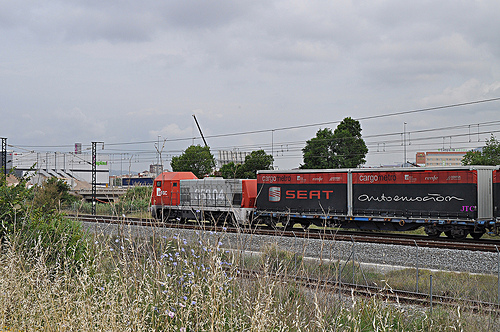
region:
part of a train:
[288, 180, 316, 215]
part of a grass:
[173, 250, 199, 280]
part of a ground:
[382, 224, 415, 275]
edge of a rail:
[386, 218, 416, 255]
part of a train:
[381, 144, 421, 231]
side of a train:
[308, 166, 351, 233]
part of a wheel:
[466, 225, 483, 242]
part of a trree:
[321, 87, 394, 164]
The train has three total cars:
[150, 162, 496, 237]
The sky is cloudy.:
[0, 0, 499, 172]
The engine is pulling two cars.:
[149, 166, 497, 238]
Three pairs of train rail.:
[63, 213, 498, 315]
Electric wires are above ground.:
[5, 95, 499, 162]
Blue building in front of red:
[107, 176, 156, 188]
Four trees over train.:
[149, 114, 499, 227]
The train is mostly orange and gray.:
[144, 165, 499, 245]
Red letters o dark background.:
[284, 190, 332, 202]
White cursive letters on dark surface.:
[358, 190, 465, 202]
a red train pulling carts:
[149, 168, 499, 250]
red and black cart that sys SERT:
[257, 168, 348, 215]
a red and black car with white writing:
[346, 168, 481, 219]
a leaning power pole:
[185, 112, 221, 179]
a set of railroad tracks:
[40, 203, 495, 256]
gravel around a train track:
[64, 217, 499, 267]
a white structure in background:
[8, 149, 112, 195]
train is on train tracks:
[148, 169, 499, 239]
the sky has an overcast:
[2, 1, 498, 167]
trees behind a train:
[172, 114, 499, 159]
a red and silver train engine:
[148, 168, 254, 225]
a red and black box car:
[255, 165, 489, 236]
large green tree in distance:
[298, 116, 373, 167]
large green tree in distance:
[235, 142, 272, 179]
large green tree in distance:
[172, 145, 215, 178]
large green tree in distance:
[463, 133, 498, 163]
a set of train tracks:
[223, 261, 498, 316]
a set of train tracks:
[65, 213, 498, 253]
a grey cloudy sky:
[1, 0, 498, 152]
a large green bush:
[27, 213, 86, 265]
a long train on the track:
[136, 173, 499, 226]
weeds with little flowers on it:
[8, 225, 385, 330]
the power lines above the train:
[12, 94, 498, 183]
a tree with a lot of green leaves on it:
[295, 117, 370, 171]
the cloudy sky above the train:
[6, 5, 498, 156]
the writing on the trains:
[269, 180, 476, 212]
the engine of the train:
[145, 169, 240, 214]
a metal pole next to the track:
[83, 141, 101, 216]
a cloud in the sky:
[185, 40, 315, 105]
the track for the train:
[66, 205, 498, 249]